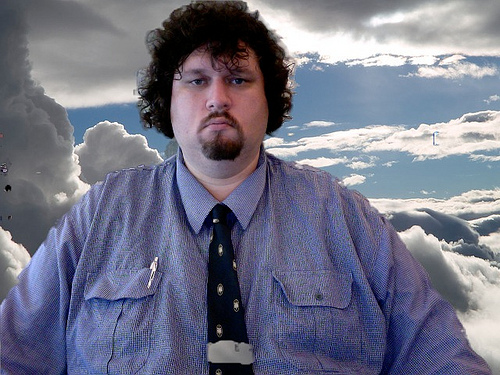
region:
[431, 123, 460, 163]
part of a cloud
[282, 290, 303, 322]
edge of a pocket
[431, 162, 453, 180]
part of the sky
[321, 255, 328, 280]
part of a shirt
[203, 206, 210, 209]
part of a colalr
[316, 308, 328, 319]
part of a shirt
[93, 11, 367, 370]
this is a man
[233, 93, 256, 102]
the man is light skinned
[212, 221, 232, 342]
this is a neck tie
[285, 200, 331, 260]
the shirt is blue in color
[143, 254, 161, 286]
this is a pen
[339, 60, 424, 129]
this is the sky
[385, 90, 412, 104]
the sky is blue in color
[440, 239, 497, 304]
these are the clouds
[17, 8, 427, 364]
A man in a tie wearing a blue button down shirt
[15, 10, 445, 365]
A man in a tie wearing a blue button down shirt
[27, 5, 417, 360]
A man in a tie wearing a blue button down shirt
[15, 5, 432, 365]
A man in a tie wearing a blue button down shirt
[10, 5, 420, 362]
A man in a tie wearing a blue button down shirt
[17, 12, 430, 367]
A man in a tie wearing a blue button down shirt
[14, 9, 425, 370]
A man in a tie wearing a blue button down shirt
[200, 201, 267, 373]
one dark patterned tie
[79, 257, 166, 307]
shiny silver pen tucked into shirt pocket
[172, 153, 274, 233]
one blue shirt collar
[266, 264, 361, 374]
one shirt pocket with button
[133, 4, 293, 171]
one dark haired man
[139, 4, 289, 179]
one Caucasian man with goatee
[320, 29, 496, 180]
sunlit clouds in blue sky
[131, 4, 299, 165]
man with curly dark hair